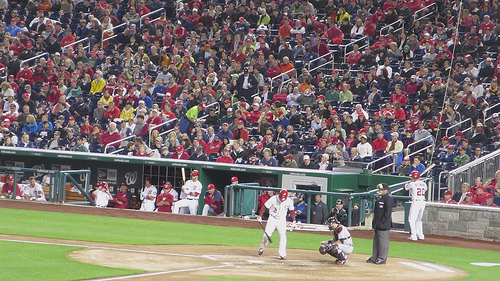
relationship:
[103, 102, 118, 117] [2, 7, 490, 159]
spectator in stands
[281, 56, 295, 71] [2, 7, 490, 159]
spectator in stands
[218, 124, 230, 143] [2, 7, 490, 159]
spectator in stands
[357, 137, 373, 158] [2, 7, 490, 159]
spectator in stands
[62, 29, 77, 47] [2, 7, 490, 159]
spectator in stands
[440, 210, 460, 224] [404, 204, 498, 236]
brick in wall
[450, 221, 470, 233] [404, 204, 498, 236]
brick in wall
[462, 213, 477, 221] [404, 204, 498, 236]
brick in wall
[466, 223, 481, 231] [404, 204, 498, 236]
brick in wall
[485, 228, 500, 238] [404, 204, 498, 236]
brick in wall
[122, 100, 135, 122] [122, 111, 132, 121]
man wearing shirt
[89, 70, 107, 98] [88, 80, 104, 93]
man wearing shirt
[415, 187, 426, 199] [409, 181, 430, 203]
number 20 on back of shirt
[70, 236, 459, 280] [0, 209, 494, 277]
circle in infield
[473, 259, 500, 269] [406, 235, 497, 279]
spot on grass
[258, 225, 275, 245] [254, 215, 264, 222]
bat in right hand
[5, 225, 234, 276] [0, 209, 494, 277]
grass on field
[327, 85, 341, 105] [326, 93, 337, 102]
man wearing shirt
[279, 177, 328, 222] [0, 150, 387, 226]
door in dugout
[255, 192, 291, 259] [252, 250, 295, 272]
batter digs into dirt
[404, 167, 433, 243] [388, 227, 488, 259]
player on deck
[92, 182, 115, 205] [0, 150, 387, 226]
teammate in dugout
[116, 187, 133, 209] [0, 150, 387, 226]
teammate in dugout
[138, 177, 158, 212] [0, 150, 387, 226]
teammate in dugout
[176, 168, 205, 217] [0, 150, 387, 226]
teammate in dugout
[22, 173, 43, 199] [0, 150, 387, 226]
teammate in dugout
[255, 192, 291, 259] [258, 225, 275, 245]
batter holds bat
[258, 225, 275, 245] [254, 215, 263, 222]
bat in right hand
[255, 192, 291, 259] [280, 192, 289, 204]
batter wearing helmet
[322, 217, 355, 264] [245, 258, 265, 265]
catcher behind home plate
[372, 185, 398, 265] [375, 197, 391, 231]
umpire wearing coat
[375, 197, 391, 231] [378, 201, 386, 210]
coat has writing